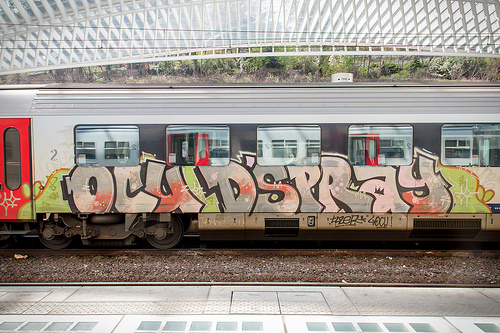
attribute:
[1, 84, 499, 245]
train — long, here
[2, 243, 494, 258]
train track — brown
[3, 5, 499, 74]
fence — illuminated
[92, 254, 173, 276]
gravel — gray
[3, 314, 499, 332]
fifteen squares — blue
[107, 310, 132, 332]
lines — black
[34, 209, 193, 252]
wheels — here, small, brown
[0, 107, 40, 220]
door — red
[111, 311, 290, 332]
stone — white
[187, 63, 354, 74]
trees — green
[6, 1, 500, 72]
ceiling — metal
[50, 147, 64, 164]
number — gray